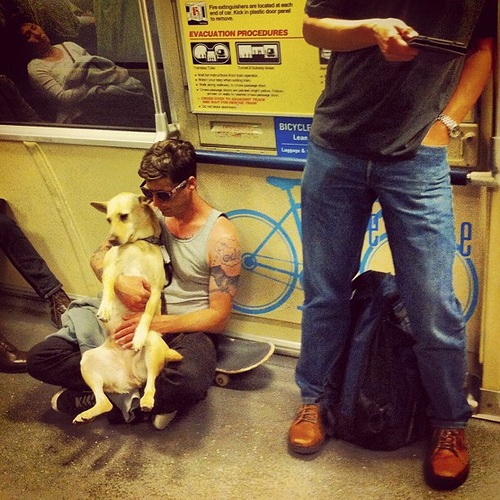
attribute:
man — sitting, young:
[28, 132, 257, 413]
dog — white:
[72, 186, 188, 430]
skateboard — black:
[214, 331, 274, 389]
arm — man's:
[161, 217, 243, 335]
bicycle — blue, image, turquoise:
[210, 171, 487, 346]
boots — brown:
[283, 407, 478, 492]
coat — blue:
[47, 293, 109, 355]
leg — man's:
[23, 293, 107, 395]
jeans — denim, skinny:
[24, 325, 221, 409]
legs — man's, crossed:
[15, 330, 225, 412]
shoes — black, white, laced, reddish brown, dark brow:
[46, 391, 180, 432]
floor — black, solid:
[4, 295, 499, 498]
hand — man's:
[421, 119, 464, 143]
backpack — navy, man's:
[325, 269, 430, 453]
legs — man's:
[301, 143, 458, 418]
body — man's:
[17, 198, 242, 428]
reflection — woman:
[9, 17, 135, 116]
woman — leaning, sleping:
[15, 13, 152, 116]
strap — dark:
[62, 43, 78, 68]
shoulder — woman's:
[50, 39, 80, 59]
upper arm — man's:
[211, 222, 243, 311]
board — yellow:
[177, 0, 335, 121]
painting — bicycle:
[206, 169, 477, 346]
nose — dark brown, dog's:
[109, 231, 122, 249]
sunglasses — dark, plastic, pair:
[136, 177, 188, 200]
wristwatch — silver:
[443, 112, 466, 136]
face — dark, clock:
[450, 123, 465, 139]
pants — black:
[91, 112, 94, 248]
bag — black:
[328, 268, 448, 464]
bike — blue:
[183, 176, 479, 333]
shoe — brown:
[287, 400, 338, 462]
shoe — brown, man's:
[425, 429, 478, 488]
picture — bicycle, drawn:
[213, 171, 481, 321]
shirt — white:
[27, 36, 96, 110]